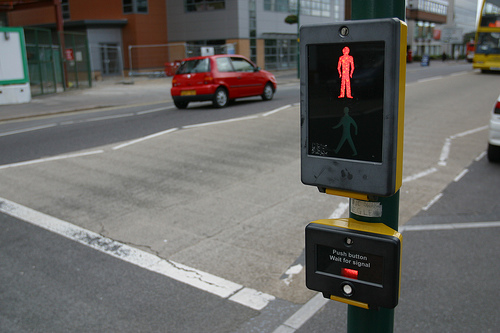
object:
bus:
[467, 2, 499, 68]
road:
[0, 63, 490, 324]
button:
[342, 283, 354, 295]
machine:
[306, 219, 400, 310]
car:
[175, 52, 277, 102]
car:
[132, 37, 296, 163]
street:
[10, 86, 149, 263]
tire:
[486, 145, 499, 167]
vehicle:
[488, 89, 498, 164]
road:
[11, 112, 307, 329]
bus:
[465, 4, 498, 81]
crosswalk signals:
[300, 14, 399, 192]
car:
[160, 42, 282, 117]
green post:
[334, 8, 417, 331]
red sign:
[62, 41, 79, 64]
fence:
[21, 27, 96, 101]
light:
[338, 261, 362, 281]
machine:
[304, 211, 404, 315]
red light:
[340, 265, 358, 277]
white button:
[341, 283, 351, 295]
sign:
[62, 49, 74, 61]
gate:
[32, 39, 107, 97]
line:
[0, 196, 275, 311]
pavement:
[0, 55, 499, 331]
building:
[41, 11, 499, 113]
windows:
[221, 42, 254, 89]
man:
[309, 52, 366, 114]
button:
[313, 234, 379, 296]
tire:
[262, 82, 274, 99]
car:
[170, 53, 277, 108]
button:
[337, 265, 364, 277]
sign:
[290, 19, 412, 314]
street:
[102, 133, 284, 263]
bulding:
[4, 5, 174, 77]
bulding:
[398, 0, 467, 64]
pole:
[341, 1, 411, 331]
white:
[487, 90, 498, 161]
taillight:
[494, 100, 499, 114]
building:
[169, 3, 490, 82]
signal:
[291, 19, 421, 173]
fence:
[21, 27, 92, 96]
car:
[151, 54, 309, 111]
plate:
[168, 77, 235, 115]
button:
[342, 282, 350, 294]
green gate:
[32, 14, 96, 98]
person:
[327, 40, 363, 106]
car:
[151, 45, 294, 113]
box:
[304, 217, 404, 311]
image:
[335, 44, 358, 100]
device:
[283, 21, 408, 330]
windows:
[413, 0, 453, 17]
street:
[0, 53, 495, 329]